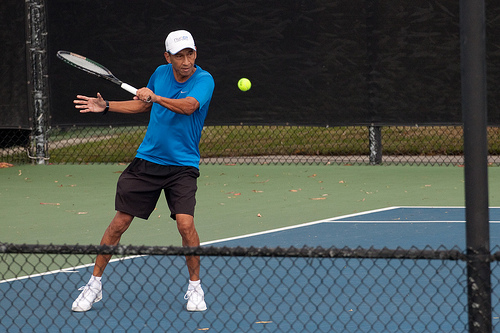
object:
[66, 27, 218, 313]
man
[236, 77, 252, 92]
ball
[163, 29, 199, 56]
hat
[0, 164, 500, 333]
tennis court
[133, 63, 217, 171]
shirt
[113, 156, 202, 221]
shorts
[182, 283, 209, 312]
shoe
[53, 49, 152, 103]
racket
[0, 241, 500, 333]
fence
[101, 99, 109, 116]
wristwatch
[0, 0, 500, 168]
fence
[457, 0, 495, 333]
pole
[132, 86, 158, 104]
hand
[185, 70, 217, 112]
sleeve